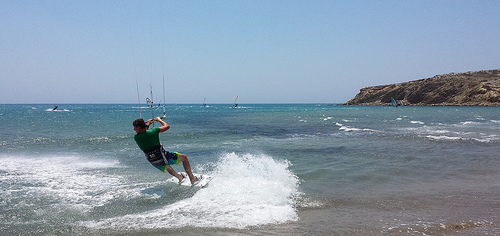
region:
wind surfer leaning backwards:
[127, 114, 213, 195]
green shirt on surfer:
[127, 127, 167, 153]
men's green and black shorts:
[141, 150, 183, 173]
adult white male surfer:
[120, 113, 208, 190]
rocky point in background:
[337, 63, 498, 115]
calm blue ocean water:
[2, 93, 498, 234]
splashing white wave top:
[80, 148, 307, 231]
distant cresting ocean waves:
[297, 108, 499, 149]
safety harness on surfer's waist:
[142, 144, 169, 165]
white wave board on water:
[160, 169, 218, 189]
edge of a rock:
[433, 77, 440, 94]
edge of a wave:
[238, 118, 258, 163]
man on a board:
[123, 109, 203, 186]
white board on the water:
[166, 167, 211, 189]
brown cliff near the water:
[344, 58, 499, 114]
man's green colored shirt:
[131, 125, 163, 150]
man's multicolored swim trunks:
[138, 143, 183, 178]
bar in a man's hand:
[141, 113, 167, 124]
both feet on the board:
[173, 171, 200, 186]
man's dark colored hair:
[131, 113, 147, 128]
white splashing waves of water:
[192, 150, 304, 224]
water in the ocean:
[2, 99, 499, 231]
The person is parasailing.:
[130, 114, 200, 187]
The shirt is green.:
[133, 126, 161, 153]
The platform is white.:
[166, 169, 214, 191]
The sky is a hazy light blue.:
[1, 0, 499, 102]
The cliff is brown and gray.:
[345, 67, 499, 107]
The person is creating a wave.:
[83, 148, 302, 234]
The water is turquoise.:
[1, 100, 498, 234]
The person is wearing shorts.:
[142, 144, 179, 173]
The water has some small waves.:
[297, 113, 497, 142]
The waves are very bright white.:
[1, 150, 303, 226]